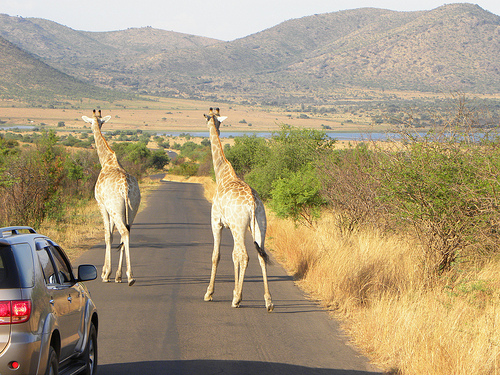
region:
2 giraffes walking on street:
[68, 93, 224, 245]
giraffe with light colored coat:
[213, 174, 280, 311]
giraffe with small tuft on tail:
[249, 230, 262, 257]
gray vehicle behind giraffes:
[43, 278, 62, 332]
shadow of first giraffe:
[288, 256, 300, 269]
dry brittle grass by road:
[342, 232, 373, 287]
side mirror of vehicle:
[71, 260, 108, 300]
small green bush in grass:
[275, 162, 315, 232]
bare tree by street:
[11, 185, 56, 214]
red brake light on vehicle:
[6, 292, 30, 337]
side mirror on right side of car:
[76, 243, 112, 295]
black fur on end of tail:
[219, 215, 284, 275]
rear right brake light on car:
[6, 300, 46, 336]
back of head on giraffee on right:
[201, 102, 237, 136]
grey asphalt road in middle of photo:
[171, 276, 262, 353]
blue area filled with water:
[348, 124, 391, 141]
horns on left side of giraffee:
[83, 103, 118, 121]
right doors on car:
[50, 242, 88, 332]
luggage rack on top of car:
[3, 216, 48, 246]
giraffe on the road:
[196, 104, 280, 309]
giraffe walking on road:
[83, 106, 151, 288]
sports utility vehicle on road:
[2, 219, 98, 372]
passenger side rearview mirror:
[76, 255, 106, 298]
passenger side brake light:
[0, 294, 31, 320]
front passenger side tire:
[84, 322, 107, 372]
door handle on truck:
[43, 297, 60, 307]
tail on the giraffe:
[244, 192, 270, 262]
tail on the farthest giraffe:
[118, 175, 138, 228]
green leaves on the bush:
[284, 172, 322, 203]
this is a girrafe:
[45, 74, 197, 286]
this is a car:
[5, 213, 97, 373]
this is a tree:
[382, 131, 491, 312]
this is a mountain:
[287, 14, 481, 121]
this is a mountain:
[3, 8, 120, 111]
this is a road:
[134, 167, 209, 344]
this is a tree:
[257, 122, 335, 228]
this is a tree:
[14, 120, 86, 237]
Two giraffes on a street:
[77, 103, 297, 319]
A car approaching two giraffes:
[0, 215, 104, 374]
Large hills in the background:
[3, 3, 497, 108]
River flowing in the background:
[5, 123, 497, 145]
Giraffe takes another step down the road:
[74, 98, 146, 285]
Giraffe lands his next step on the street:
[195, 99, 279, 319]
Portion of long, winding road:
[103, 133, 216, 371]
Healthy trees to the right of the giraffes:
[272, 138, 498, 250]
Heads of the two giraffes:
[76, 105, 255, 131]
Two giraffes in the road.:
[75, 108, 284, 306]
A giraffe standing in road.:
[183, 99, 288, 324]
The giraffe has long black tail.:
[247, 211, 274, 268]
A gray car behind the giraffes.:
[10, 228, 121, 369]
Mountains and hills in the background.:
[14, 20, 474, 88]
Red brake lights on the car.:
[3, 300, 32, 320]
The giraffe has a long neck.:
[203, 101, 239, 170]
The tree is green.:
[273, 156, 327, 237]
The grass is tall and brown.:
[312, 248, 494, 353]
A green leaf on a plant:
[285, 185, 291, 188]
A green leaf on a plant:
[303, 175, 306, 177]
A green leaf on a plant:
[293, 195, 294, 196]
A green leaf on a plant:
[312, 186, 314, 188]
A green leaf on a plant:
[240, 150, 242, 151]